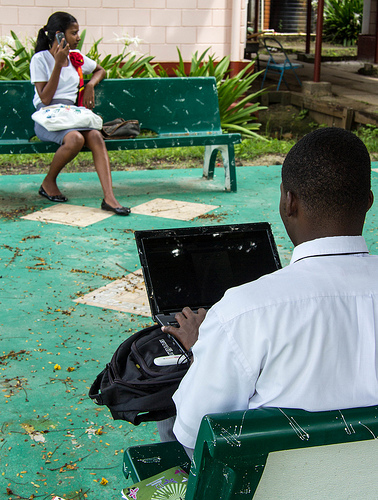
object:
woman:
[30, 11, 132, 217]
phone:
[56, 31, 69, 51]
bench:
[0, 78, 242, 192]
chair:
[261, 36, 305, 92]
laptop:
[134, 221, 283, 362]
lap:
[156, 359, 189, 440]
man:
[160, 127, 376, 451]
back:
[308, 143, 367, 200]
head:
[275, 130, 373, 249]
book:
[122, 459, 192, 499]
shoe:
[39, 186, 69, 202]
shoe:
[101, 199, 132, 215]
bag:
[101, 117, 141, 139]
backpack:
[88, 324, 194, 427]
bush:
[3, 31, 38, 81]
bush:
[77, 29, 158, 78]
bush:
[145, 51, 273, 142]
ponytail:
[35, 24, 51, 54]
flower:
[105, 30, 142, 48]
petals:
[113, 28, 122, 41]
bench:
[122, 405, 377, 499]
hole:
[28, 135, 42, 144]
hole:
[135, 128, 160, 138]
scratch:
[137, 455, 161, 464]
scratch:
[221, 410, 248, 451]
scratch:
[278, 407, 311, 440]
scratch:
[338, 409, 356, 436]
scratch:
[234, 482, 253, 496]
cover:
[123, 464, 193, 499]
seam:
[222, 281, 376, 326]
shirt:
[172, 235, 377, 447]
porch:
[247, 56, 378, 116]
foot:
[37, 181, 67, 203]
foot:
[99, 201, 132, 219]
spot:
[171, 248, 181, 257]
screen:
[142, 230, 279, 314]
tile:
[124, 198, 221, 223]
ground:
[0, 133, 376, 499]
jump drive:
[153, 354, 193, 368]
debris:
[48, 360, 62, 381]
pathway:
[0, 161, 377, 500]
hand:
[54, 38, 70, 64]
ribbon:
[70, 50, 86, 108]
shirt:
[27, 50, 99, 104]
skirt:
[34, 99, 101, 144]